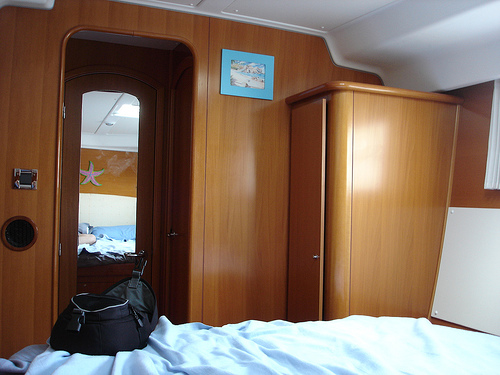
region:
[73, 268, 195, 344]
the bag is on the bed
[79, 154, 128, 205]
there is a star sign on the wall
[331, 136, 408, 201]
there is light shinning on the wall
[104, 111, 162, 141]
the ceiling has light on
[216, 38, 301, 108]
the photo on the wall has a blue frame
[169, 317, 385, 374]
the bed is not spread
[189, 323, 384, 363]
the bedcover is white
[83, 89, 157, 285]
there is a mirror on the door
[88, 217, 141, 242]
there is a blue pillow on the bed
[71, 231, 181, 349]
the bag is open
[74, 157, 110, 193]
star fish on wood wall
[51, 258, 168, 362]
black bag on bed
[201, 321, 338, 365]
wrinkled blanket on bed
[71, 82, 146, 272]
mirror across from bed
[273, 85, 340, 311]
closet with door slightly ajar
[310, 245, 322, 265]
knob on closet door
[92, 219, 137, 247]
blue pillows in mirror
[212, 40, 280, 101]
blue mat around picture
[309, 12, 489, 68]
uneven white ceiling above bedroom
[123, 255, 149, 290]
strap on side of bag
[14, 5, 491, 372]
Bed in a bethroom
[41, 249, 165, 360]
Black bag on the bed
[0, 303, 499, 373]
Bed is cover by a white comforter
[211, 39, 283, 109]
Blue picture on a closet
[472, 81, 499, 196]
White curtain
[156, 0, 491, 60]
Ceiling of room is white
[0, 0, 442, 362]
Closer is brown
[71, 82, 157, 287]
Closet has a mirror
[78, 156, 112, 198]
A sea star is reflected in the mirror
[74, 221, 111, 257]
A person is in the room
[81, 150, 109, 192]
Star fish on door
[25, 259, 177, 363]
Black bag on bed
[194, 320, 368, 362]
White blanket on bed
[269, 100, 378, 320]
Wood door in corner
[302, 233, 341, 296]
Silver knob on door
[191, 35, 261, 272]
Wall is brown wood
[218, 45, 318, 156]
Blue picture frame hung on wall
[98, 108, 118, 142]
Ceiling is white in color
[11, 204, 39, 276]
Circle on side of wall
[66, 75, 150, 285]
Door has glass in the middle of it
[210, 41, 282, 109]
Picture in blue frame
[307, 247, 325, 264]
Small metal door knob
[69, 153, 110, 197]
Medium sized starfish shaped artwork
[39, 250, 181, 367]
Medium sized black duffel bag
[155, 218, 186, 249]
Small silver door knob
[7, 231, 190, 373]
Black bag sitting on bed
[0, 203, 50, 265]
Black speaker with brown trim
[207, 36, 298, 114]
Photograph in a blue frame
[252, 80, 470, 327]
Closet with brown door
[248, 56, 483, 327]
Wooden closet with brown door